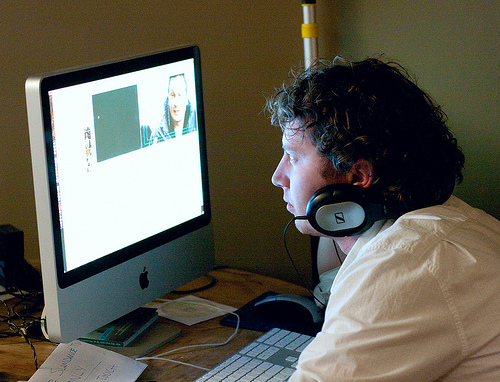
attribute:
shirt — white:
[246, 222, 497, 381]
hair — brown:
[224, 25, 490, 236]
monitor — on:
[20, 50, 238, 320]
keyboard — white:
[166, 306, 334, 380]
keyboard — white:
[166, 297, 363, 377]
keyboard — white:
[141, 298, 374, 378]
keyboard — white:
[109, 290, 399, 380]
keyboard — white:
[115, 303, 369, 379]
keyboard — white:
[151, 313, 409, 379]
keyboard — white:
[112, 283, 358, 379]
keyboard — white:
[162, 305, 363, 379]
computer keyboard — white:
[143, 299, 357, 378]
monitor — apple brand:
[17, 26, 209, 357]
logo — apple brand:
[125, 263, 166, 303]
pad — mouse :
[226, 289, 311, 322]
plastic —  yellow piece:
[300, 18, 314, 38]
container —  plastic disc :
[4, 223, 47, 333]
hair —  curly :
[287, 92, 422, 144]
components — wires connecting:
[22, 42, 322, 374]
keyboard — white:
[201, 322, 308, 370]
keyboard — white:
[184, 317, 336, 378]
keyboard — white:
[184, 326, 309, 380]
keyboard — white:
[209, 328, 328, 380]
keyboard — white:
[208, 325, 309, 380]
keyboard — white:
[209, 332, 305, 379]